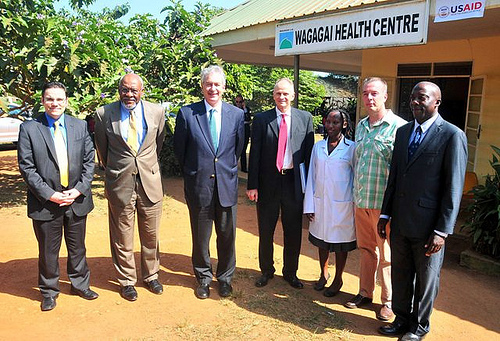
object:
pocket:
[329, 198, 355, 230]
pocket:
[310, 195, 323, 225]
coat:
[301, 128, 358, 246]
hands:
[48, 189, 76, 208]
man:
[14, 79, 99, 312]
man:
[245, 74, 317, 290]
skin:
[320, 115, 355, 295]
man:
[170, 65, 247, 300]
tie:
[206, 104, 218, 150]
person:
[373, 77, 471, 341]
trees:
[1, 1, 320, 173]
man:
[14, 79, 99, 316]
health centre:
[334, 13, 422, 42]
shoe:
[38, 297, 56, 314]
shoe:
[70, 286, 99, 302]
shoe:
[119, 285, 139, 302]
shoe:
[148, 281, 166, 297]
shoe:
[194, 282, 212, 299]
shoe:
[214, 280, 234, 297]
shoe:
[253, 272, 274, 288]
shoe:
[281, 274, 306, 290]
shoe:
[374, 322, 406, 336]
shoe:
[395, 332, 418, 339]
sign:
[268, 0, 433, 58]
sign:
[428, 0, 492, 23]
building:
[194, 0, 500, 270]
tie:
[274, 112, 289, 176]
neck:
[272, 103, 295, 111]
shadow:
[0, 248, 392, 339]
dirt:
[0, 146, 500, 337]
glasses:
[39, 95, 68, 105]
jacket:
[171, 94, 249, 211]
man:
[93, 70, 170, 303]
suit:
[87, 102, 173, 285]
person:
[346, 72, 409, 324]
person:
[298, 104, 359, 299]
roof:
[199, 0, 498, 45]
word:
[332, 16, 372, 41]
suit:
[16, 109, 99, 299]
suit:
[376, 118, 466, 337]